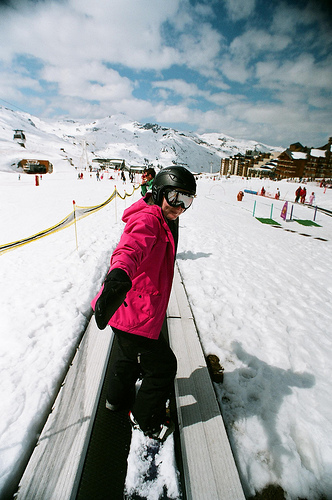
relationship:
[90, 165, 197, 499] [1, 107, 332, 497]
woman in snow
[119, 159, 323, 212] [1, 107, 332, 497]
people in snow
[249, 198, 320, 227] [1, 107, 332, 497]
posts in snow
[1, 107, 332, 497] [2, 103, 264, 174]
snow covering mountains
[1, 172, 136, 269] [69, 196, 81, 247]
yellow tape on reflectors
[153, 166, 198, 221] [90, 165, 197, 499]
head of a woman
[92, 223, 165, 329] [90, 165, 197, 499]
arm of a woman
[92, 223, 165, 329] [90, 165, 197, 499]
arm on woman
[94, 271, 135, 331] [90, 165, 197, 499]
hand of woman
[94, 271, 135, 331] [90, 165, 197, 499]
hand of a woman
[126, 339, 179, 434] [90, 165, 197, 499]
leg of woman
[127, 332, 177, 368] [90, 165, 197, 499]
thigh of a woman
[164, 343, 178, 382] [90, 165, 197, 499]
knee of a woman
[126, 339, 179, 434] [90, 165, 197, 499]
leg of a woman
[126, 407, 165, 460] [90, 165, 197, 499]
feet of a woman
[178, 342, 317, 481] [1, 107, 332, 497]
shadow on ground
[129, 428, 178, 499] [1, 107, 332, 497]
shoe white with snow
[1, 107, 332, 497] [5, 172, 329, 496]
snow covers ground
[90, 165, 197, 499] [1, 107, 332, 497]
woman stands in snow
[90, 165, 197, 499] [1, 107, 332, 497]
woman skis in snow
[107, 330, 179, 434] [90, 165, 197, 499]
legs of woman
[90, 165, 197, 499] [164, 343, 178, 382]
woman bends her knee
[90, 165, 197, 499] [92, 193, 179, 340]
woman wearing s jacket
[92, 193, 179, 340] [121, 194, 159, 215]
jacket has a hood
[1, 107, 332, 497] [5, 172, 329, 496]
snow over ground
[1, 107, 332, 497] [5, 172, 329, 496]
snow covering ground